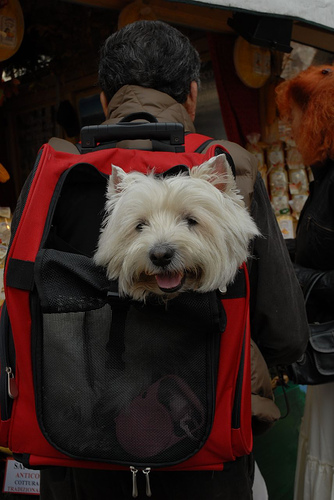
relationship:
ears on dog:
[104, 152, 231, 200] [102, 156, 248, 300]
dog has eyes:
[92, 153, 267, 303] [133, 215, 198, 231]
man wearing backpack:
[0, 19, 310, 498] [31, 140, 262, 323]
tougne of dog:
[160, 275, 178, 285] [92, 153, 267, 303]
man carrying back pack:
[0, 19, 310, 498] [0, 132, 253, 474]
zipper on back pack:
[131, 463, 139, 498] [0, 132, 253, 474]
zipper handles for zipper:
[128, 465, 151, 496] [202, 341, 217, 446]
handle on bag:
[78, 120, 185, 147] [5, 104, 261, 467]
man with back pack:
[0, 19, 310, 498] [0, 132, 253, 474]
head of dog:
[90, 150, 267, 305] [112, 173, 201, 251]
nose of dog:
[148, 247, 174, 263] [92, 153, 267, 303]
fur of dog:
[105, 181, 166, 248] [92, 153, 267, 303]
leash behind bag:
[114, 372, 206, 458] [5, 104, 261, 467]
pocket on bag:
[39, 298, 205, 462] [5, 104, 261, 467]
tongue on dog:
[155, 272, 181, 287] [92, 153, 267, 303]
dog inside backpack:
[92, 153, 267, 303] [2, 142, 253, 473]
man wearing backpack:
[0, 19, 310, 498] [0, 115, 254, 496]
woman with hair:
[273, 75, 333, 333] [277, 64, 333, 163]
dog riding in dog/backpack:
[92, 153, 267, 303] [1, 119, 250, 484]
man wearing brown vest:
[34, 19, 310, 499] [44, 82, 281, 440]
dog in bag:
[92, 153, 267, 303] [5, 104, 261, 467]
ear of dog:
[187, 150, 237, 198] [101, 148, 249, 338]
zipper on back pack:
[125, 463, 141, 498] [49, 115, 330, 475]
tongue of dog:
[154, 272, 183, 287] [93, 153, 267, 415]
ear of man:
[190, 77, 207, 115] [0, 19, 310, 498]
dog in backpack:
[92, 153, 267, 303] [0, 115, 254, 496]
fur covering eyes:
[105, 181, 166, 248] [132, 212, 205, 232]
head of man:
[98, 22, 214, 145] [34, 19, 310, 499]